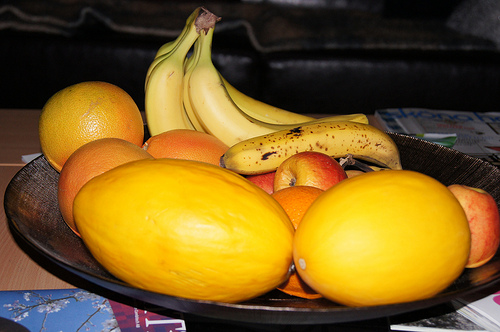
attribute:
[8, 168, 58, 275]
bowl — brown, fruit bowl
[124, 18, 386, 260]
fruit — mixed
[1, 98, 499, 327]
table — coffee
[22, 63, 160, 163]
fruit — orange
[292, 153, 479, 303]
fruit — orange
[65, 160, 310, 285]
fruit — orange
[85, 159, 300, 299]
food — yellow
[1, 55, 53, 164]
table — tan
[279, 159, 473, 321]
melon — yellow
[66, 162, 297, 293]
melon — yellow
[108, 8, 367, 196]
bananas — bunches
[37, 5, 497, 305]
fruit — fresh, stacked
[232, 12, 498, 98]
couch — black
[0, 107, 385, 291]
table — wooden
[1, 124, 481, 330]
plate — brown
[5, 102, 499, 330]
plate — dark, brown